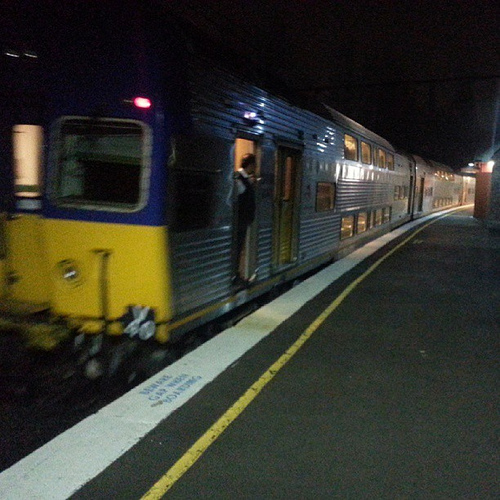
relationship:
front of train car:
[11, 49, 151, 332] [23, 54, 417, 309]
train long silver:
[7, 93, 478, 331] [243, 117, 337, 143]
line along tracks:
[138, 217, 440, 499] [5, 360, 90, 435]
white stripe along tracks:
[141, 341, 233, 407] [5, 360, 90, 435]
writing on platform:
[134, 366, 208, 414] [229, 221, 500, 500]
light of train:
[129, 93, 161, 111] [7, 93, 478, 331]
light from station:
[478, 160, 497, 177] [391, 110, 494, 268]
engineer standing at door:
[230, 147, 264, 300] [226, 125, 264, 155]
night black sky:
[269, 5, 324, 63] [349, 1, 498, 64]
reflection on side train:
[336, 159, 443, 197] [7, 93, 478, 331]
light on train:
[129, 93, 161, 111] [7, 93, 478, 331]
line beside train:
[138, 217, 440, 499] [7, 93, 478, 331]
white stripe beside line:
[0, 204, 478, 499] [138, 217, 440, 499]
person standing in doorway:
[230, 147, 264, 300] [234, 133, 261, 159]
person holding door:
[230, 147, 264, 300] [226, 125, 264, 155]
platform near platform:
[0, 211, 500, 500] [229, 221, 500, 500]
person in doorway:
[230, 147, 264, 300] [234, 133, 261, 159]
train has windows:
[7, 93, 478, 331] [337, 131, 403, 173]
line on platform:
[179, 412, 239, 463] [0, 211, 500, 500]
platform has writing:
[0, 211, 500, 500] [134, 366, 208, 414]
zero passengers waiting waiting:
[416, 198, 500, 346] [393, 290, 453, 371]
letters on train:
[117, 305, 157, 350] [7, 93, 478, 331]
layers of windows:
[341, 131, 396, 237] [337, 131, 403, 173]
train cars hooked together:
[78, 57, 481, 232] [343, 161, 461, 203]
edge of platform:
[285, 263, 334, 318] [229, 221, 500, 500]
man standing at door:
[230, 147, 264, 300] [226, 125, 264, 155]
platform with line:
[229, 221, 500, 500] [138, 217, 440, 499]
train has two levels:
[7, 93, 478, 331] [336, 127, 364, 247]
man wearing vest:
[230, 147, 264, 300] [237, 175, 259, 230]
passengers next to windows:
[346, 145, 356, 159] [337, 131, 403, 173]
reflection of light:
[336, 159, 443, 197] [482, 160, 496, 177]